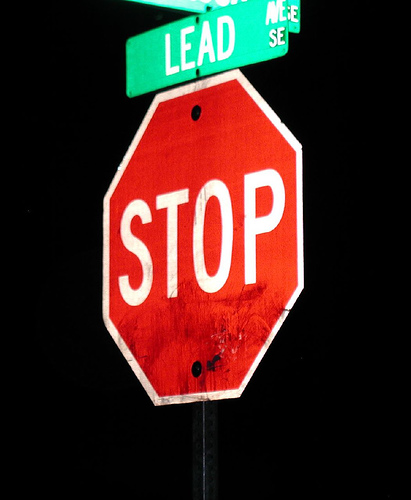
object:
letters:
[213, 15, 232, 62]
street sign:
[125, 2, 291, 98]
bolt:
[193, 14, 199, 26]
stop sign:
[101, 68, 303, 411]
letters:
[243, 168, 285, 285]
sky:
[0, 1, 409, 500]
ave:
[265, 0, 287, 26]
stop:
[119, 170, 286, 306]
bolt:
[191, 105, 201, 123]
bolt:
[191, 359, 203, 378]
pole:
[195, 403, 215, 498]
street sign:
[125, 0, 301, 34]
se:
[268, 29, 285, 51]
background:
[0, 0, 410, 498]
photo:
[0, 1, 410, 499]